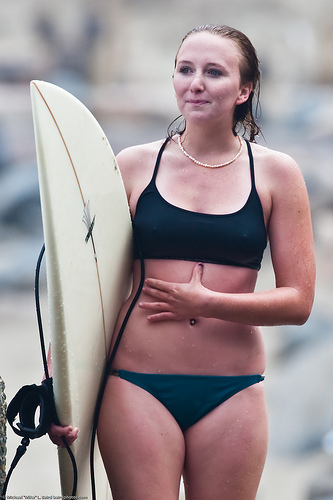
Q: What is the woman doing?
A: Going to go surfing.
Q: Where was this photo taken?
A: The beach.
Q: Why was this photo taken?
A: For a souvenir.